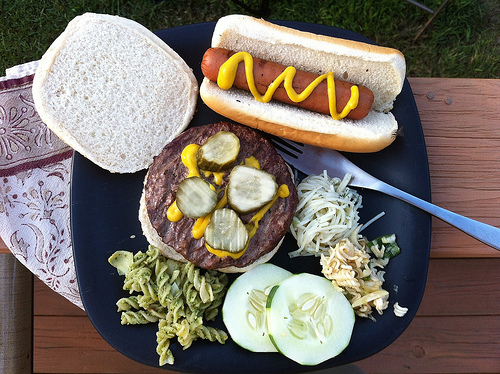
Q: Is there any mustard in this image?
A: Yes, there is mustard.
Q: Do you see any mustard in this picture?
A: Yes, there is mustard.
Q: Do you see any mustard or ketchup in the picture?
A: Yes, there is mustard.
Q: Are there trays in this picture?
A: No, there are no trays.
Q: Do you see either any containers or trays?
A: No, there are no trays or containers.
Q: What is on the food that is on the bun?
A: The mustard is on the hot dog.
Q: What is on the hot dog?
A: The mustard is on the hot dog.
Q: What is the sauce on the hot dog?
A: The sauce is mustard.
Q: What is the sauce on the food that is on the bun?
A: The sauce is mustard.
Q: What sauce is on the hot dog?
A: The sauce is mustard.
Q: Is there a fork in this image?
A: Yes, there is a fork.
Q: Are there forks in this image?
A: Yes, there is a fork.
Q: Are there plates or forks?
A: Yes, there is a fork.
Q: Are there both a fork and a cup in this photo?
A: No, there is a fork but no cups.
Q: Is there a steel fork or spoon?
A: Yes, there is a steel fork.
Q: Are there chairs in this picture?
A: No, there are no chairs.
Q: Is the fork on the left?
A: No, the fork is on the right of the image.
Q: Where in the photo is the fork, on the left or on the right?
A: The fork is on the right of the image.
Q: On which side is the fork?
A: The fork is on the right of the image.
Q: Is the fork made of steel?
A: Yes, the fork is made of steel.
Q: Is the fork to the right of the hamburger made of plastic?
A: No, the fork is made of steel.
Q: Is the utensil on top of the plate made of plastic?
A: No, the fork is made of steel.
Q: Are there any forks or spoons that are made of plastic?
A: No, there is a fork but it is made of steel.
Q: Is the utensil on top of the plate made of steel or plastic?
A: The fork is made of steel.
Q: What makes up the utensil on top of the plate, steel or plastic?
A: The fork is made of steel.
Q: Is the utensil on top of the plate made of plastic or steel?
A: The fork is made of steel.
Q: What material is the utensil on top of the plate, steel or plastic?
A: The fork is made of steel.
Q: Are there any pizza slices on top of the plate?
A: No, there is a fork on top of the plate.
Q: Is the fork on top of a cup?
A: No, the fork is on top of a plate.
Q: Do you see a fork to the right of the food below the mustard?
A: Yes, there is a fork to the right of the hamburger.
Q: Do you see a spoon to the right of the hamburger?
A: No, there is a fork to the right of the hamburger.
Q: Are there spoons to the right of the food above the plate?
A: No, there is a fork to the right of the hamburger.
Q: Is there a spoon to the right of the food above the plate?
A: No, there is a fork to the right of the hamburger.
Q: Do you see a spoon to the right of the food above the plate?
A: No, there is a fork to the right of the hamburger.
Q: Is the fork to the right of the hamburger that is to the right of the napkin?
A: Yes, the fork is to the right of the hamburger.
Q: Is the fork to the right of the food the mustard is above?
A: Yes, the fork is to the right of the hamburger.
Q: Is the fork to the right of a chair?
A: No, the fork is to the right of the hamburger.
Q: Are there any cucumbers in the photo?
A: Yes, there is a cucumber.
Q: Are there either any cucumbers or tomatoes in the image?
A: Yes, there is a cucumber.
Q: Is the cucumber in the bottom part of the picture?
A: Yes, the cucumber is in the bottom of the image.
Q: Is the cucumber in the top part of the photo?
A: No, the cucumber is in the bottom of the image.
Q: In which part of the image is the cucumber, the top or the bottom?
A: The cucumber is in the bottom of the image.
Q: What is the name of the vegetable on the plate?
A: The vegetable is a cucumber.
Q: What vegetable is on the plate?
A: The vegetable is a cucumber.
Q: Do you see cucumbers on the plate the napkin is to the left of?
A: Yes, there is a cucumber on the plate.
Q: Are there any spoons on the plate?
A: No, there is a cucumber on the plate.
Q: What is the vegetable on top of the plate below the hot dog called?
A: The vegetable is a cucumber.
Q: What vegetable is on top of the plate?
A: The vegetable is a cucumber.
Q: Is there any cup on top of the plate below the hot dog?
A: No, there is a cucumber on top of the plate.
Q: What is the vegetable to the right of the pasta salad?
A: The vegetable is a cucumber.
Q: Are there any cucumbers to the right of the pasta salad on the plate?
A: Yes, there is a cucumber to the right of the pasta salad.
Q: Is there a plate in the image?
A: Yes, there is a plate.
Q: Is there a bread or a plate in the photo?
A: Yes, there is a plate.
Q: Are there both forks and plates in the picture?
A: Yes, there are both a plate and a fork.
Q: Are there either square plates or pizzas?
A: Yes, there is a square plate.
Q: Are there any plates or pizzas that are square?
A: Yes, the plate is square.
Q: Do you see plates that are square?
A: Yes, there is a square plate.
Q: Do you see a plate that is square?
A: Yes, there is a plate that is square.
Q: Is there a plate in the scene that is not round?
A: Yes, there is a square plate.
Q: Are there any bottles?
A: No, there are no bottles.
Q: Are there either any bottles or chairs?
A: No, there are no bottles or chairs.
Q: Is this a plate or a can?
A: This is a plate.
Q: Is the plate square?
A: Yes, the plate is square.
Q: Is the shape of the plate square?
A: Yes, the plate is square.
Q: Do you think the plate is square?
A: Yes, the plate is square.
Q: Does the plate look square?
A: Yes, the plate is square.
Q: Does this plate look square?
A: Yes, the plate is square.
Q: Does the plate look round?
A: No, the plate is square.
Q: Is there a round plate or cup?
A: No, there is a plate but it is square.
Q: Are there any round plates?
A: No, there is a plate but it is square.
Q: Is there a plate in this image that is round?
A: No, there is a plate but it is square.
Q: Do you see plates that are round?
A: No, there is a plate but it is square.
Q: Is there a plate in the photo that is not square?
A: No, there is a plate but it is square.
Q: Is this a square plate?
A: Yes, this is a square plate.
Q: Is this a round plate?
A: No, this is a square plate.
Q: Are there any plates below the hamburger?
A: Yes, there is a plate below the hamburger.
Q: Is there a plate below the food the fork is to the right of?
A: Yes, there is a plate below the hamburger.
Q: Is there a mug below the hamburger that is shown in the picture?
A: No, there is a plate below the hamburger.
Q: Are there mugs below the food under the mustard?
A: No, there is a plate below the hamburger.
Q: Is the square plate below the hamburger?
A: Yes, the plate is below the hamburger.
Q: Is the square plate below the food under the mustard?
A: Yes, the plate is below the hamburger.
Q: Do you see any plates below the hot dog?
A: Yes, there is a plate below the hot dog.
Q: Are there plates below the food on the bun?
A: Yes, there is a plate below the hot dog.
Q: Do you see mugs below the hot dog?
A: No, there is a plate below the hot dog.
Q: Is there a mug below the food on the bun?
A: No, there is a plate below the hot dog.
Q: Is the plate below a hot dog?
A: Yes, the plate is below a hot dog.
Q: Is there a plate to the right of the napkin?
A: Yes, there is a plate to the right of the napkin.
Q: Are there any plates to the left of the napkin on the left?
A: No, the plate is to the right of the napkin.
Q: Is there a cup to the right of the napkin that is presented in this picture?
A: No, there is a plate to the right of the napkin.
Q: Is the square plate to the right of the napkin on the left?
A: Yes, the plate is to the right of the napkin.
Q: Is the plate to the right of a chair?
A: No, the plate is to the right of the napkin.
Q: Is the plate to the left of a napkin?
A: No, the plate is to the right of a napkin.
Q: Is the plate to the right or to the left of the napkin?
A: The plate is to the right of the napkin.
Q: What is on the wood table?
A: The plate is on the table.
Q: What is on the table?
A: The plate is on the table.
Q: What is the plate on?
A: The plate is on the table.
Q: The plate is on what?
A: The plate is on the table.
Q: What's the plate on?
A: The plate is on the table.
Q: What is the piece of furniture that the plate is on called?
A: The piece of furniture is a table.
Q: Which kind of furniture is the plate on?
A: The plate is on the table.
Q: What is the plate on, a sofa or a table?
A: The plate is on a table.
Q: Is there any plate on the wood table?
A: Yes, there is a plate on the table.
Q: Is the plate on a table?
A: Yes, the plate is on a table.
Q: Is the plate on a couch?
A: No, the plate is on a table.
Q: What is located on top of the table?
A: The plate is on top of the table.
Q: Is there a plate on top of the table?
A: Yes, there is a plate on top of the table.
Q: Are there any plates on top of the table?
A: Yes, there is a plate on top of the table.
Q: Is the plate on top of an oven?
A: No, the plate is on top of the table.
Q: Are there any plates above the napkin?
A: Yes, there is a plate above the napkin.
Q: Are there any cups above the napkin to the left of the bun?
A: No, there is a plate above the napkin.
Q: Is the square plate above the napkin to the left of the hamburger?
A: Yes, the plate is above the napkin.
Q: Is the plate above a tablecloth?
A: No, the plate is above the napkin.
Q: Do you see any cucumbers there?
A: Yes, there is a cucumber.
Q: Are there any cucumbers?
A: Yes, there is a cucumber.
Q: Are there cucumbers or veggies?
A: Yes, there is a cucumber.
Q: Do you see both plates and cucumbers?
A: Yes, there are both a cucumber and a plate.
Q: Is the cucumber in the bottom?
A: Yes, the cucumber is in the bottom of the image.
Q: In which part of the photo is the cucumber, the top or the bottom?
A: The cucumber is in the bottom of the image.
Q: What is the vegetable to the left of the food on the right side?
A: The vegetable is a cucumber.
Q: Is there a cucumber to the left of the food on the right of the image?
A: Yes, there is a cucumber to the left of the food.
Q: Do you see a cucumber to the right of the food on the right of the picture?
A: No, the cucumber is to the left of the food.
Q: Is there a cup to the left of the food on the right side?
A: No, there is a cucumber to the left of the food.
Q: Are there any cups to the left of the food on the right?
A: No, there is a cucumber to the left of the food.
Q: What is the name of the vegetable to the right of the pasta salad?
A: The vegetable is a cucumber.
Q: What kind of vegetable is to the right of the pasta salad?
A: The vegetable is a cucumber.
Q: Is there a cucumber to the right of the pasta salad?
A: Yes, there is a cucumber to the right of the pasta salad.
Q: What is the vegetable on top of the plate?
A: The vegetable is a cucumber.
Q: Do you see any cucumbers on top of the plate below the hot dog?
A: Yes, there is a cucumber on top of the plate.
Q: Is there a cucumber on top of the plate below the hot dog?
A: Yes, there is a cucumber on top of the plate.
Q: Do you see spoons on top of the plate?
A: No, there is a cucumber on top of the plate.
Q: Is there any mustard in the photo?
A: Yes, there is mustard.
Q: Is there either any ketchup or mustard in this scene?
A: Yes, there is mustard.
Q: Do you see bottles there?
A: No, there are no bottles.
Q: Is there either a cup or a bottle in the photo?
A: No, there are no bottles or cups.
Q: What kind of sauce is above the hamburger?
A: The sauce is mustard.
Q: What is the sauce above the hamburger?
A: The sauce is mustard.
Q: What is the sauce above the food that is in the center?
A: The sauce is mustard.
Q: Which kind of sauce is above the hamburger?
A: The sauce is mustard.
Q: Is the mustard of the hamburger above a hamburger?
A: Yes, the mustard is above a hamburger.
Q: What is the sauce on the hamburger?
A: The sauce is mustard.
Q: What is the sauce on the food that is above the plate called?
A: The sauce is mustard.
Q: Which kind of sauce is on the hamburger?
A: The sauce is mustard.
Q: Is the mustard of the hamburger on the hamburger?
A: Yes, the mustard is on the hamburger.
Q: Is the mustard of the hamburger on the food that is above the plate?
A: Yes, the mustard is on the hamburger.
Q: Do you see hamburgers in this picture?
A: Yes, there is a hamburger.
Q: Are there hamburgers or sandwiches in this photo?
A: Yes, there is a hamburger.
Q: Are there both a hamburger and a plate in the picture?
A: Yes, there are both a hamburger and a plate.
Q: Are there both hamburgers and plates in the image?
A: Yes, there are both a hamburger and a plate.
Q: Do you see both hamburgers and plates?
A: Yes, there are both a hamburger and a plate.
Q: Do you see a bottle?
A: No, there are no bottles.